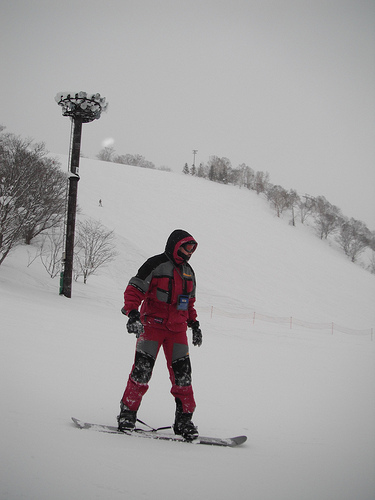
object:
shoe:
[116, 414, 137, 433]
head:
[165, 227, 199, 267]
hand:
[126, 310, 142, 335]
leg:
[120, 326, 159, 418]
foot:
[115, 410, 139, 430]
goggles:
[179, 246, 197, 261]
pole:
[57, 118, 81, 297]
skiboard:
[69, 417, 248, 446]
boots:
[170, 407, 199, 442]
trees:
[315, 197, 344, 241]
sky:
[0, 0, 374, 234]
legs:
[162, 337, 197, 426]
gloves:
[189, 319, 203, 348]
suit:
[118, 228, 203, 430]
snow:
[0, 153, 374, 499]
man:
[114, 228, 204, 444]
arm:
[120, 257, 158, 321]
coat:
[121, 230, 200, 330]